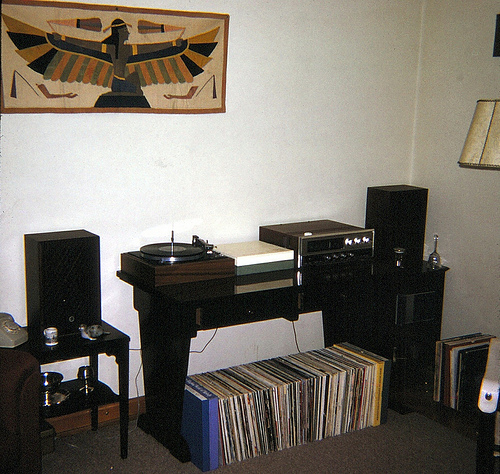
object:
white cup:
[42, 323, 59, 345]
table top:
[18, 320, 131, 359]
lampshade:
[456, 97, 498, 169]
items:
[72, 364, 100, 393]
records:
[259, 386, 272, 453]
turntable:
[118, 227, 236, 289]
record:
[139, 240, 204, 260]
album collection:
[183, 342, 393, 470]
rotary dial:
[3, 320, 20, 333]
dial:
[363, 235, 370, 243]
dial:
[354, 237, 361, 244]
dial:
[344, 237, 353, 246]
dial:
[349, 252, 354, 257]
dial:
[332, 253, 338, 259]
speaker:
[366, 177, 441, 288]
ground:
[388, 53, 421, 76]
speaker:
[23, 228, 103, 344]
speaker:
[365, 182, 428, 269]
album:
[180, 383, 208, 471]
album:
[205, 389, 220, 470]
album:
[332, 373, 346, 438]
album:
[378, 357, 391, 425]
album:
[219, 396, 231, 463]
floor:
[40, 408, 477, 472]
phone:
[1, 311, 27, 347]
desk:
[116, 249, 449, 464]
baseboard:
[45, 394, 148, 432]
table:
[8, 308, 144, 471]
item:
[75, 312, 111, 340]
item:
[21, 229, 105, 330]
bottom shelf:
[42, 375, 117, 417]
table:
[18, 320, 130, 459]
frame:
[0, 0, 230, 117]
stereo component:
[258, 218, 374, 269]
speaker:
[14, 216, 122, 360]